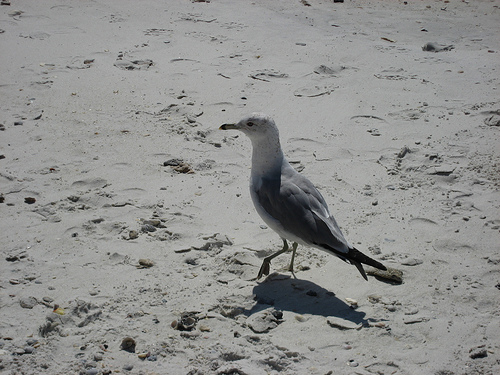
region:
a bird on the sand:
[217, 86, 427, 333]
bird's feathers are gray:
[250, 176, 350, 263]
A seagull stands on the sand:
[215, 105, 395, 292]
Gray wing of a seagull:
[255, 170, 385, 280]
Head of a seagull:
[215, 110, 280, 170]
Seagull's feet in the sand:
[250, 230, 300, 285]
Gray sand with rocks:
[50, 190, 185, 310]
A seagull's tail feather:
[315, 235, 385, 285]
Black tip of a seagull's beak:
[215, 115, 230, 130]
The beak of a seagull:
[215, 115, 235, 130]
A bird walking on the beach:
[215, 106, 385, 278]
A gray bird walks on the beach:
[217, 112, 387, 288]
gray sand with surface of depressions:
[15, 16, 482, 362]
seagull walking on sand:
[211, 110, 391, 292]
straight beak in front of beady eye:
[215, 111, 275, 133]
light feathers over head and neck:
[216, 110, 291, 185]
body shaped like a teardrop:
[251, 165, 347, 255]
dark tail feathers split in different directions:
[345, 245, 385, 280]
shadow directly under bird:
[216, 111, 376, 326]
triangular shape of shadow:
[250, 261, 365, 326]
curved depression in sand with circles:
[245, 60, 290, 85]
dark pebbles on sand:
[121, 203, 202, 271]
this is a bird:
[218, 98, 403, 300]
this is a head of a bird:
[221, 101, 278, 153]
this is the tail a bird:
[340, 220, 390, 295]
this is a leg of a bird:
[286, 244, 298, 280]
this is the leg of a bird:
[251, 234, 281, 279]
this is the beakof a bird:
[211, 110, 239, 147]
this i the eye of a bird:
[245, 115, 260, 132]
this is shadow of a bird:
[249, 270, 356, 325]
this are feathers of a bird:
[269, 165, 299, 220]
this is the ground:
[67, 99, 112, 259]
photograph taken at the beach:
[19, 22, 472, 353]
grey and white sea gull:
[211, 105, 397, 327]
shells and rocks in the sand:
[20, 98, 211, 364]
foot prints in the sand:
[89, 3, 399, 95]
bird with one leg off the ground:
[187, 92, 389, 294]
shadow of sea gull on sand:
[187, 257, 364, 335]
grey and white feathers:
[252, 165, 400, 281]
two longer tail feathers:
[332, 241, 401, 282]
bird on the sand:
[213, 113, 371, 279]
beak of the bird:
[211, 118, 244, 137]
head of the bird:
[232, 108, 280, 137]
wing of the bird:
[286, 192, 323, 238]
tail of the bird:
[352, 254, 387, 271]